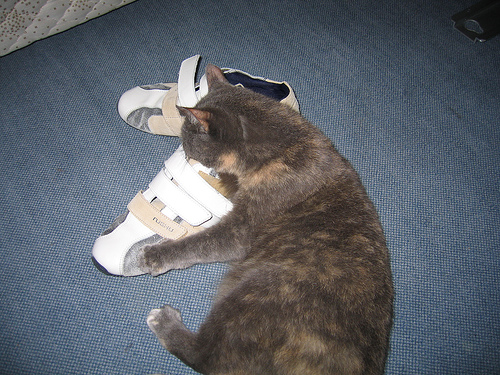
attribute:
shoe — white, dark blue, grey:
[91, 140, 241, 282]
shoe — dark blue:
[116, 55, 320, 136]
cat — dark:
[141, 62, 397, 373]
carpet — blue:
[2, 0, 499, 373]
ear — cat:
[175, 102, 210, 134]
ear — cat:
[200, 62, 225, 88]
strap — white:
[122, 150, 234, 239]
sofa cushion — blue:
[0, 2, 499, 372]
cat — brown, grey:
[130, 74, 418, 374]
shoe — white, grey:
[111, 50, 306, 142]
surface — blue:
[0, 2, 499, 372]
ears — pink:
[180, 49, 236, 149]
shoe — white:
[85, 144, 246, 272]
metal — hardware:
[451, 10, 488, 50]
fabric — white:
[0, 0, 130, 57]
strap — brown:
[129, 180, 200, 234]